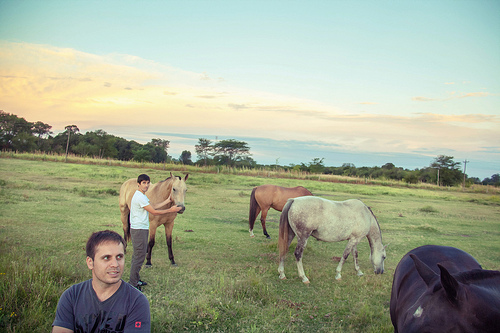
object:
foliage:
[481, 172, 500, 188]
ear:
[406, 252, 439, 288]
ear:
[435, 263, 462, 305]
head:
[396, 251, 490, 333]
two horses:
[247, 183, 393, 284]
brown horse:
[248, 183, 316, 239]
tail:
[248, 186, 257, 231]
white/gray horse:
[277, 194, 390, 286]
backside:
[253, 185, 268, 210]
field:
[0, 150, 500, 333]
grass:
[0, 147, 500, 333]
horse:
[386, 243, 499, 333]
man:
[48, 227, 153, 333]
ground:
[0, 150, 500, 333]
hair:
[276, 198, 294, 263]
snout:
[174, 203, 186, 214]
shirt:
[49, 278, 151, 333]